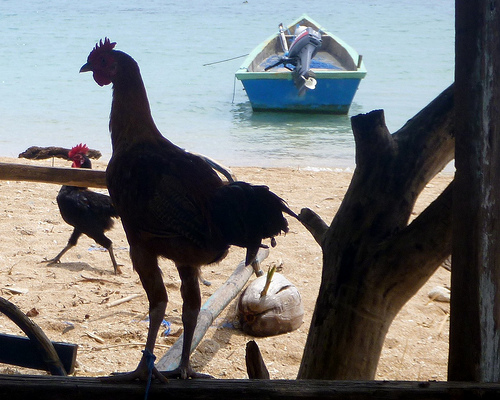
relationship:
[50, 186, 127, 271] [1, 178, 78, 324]
chicken on beach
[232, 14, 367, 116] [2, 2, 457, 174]
boat in water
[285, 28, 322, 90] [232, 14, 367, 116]
motor on boat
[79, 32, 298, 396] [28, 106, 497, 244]
chicken walking on beach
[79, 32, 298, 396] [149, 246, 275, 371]
chicken standing on log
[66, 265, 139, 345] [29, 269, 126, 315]
sticks on sand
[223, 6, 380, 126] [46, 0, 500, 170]
boat in water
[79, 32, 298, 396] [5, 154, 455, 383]
chicken on sand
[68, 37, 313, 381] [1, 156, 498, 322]
chicken on beach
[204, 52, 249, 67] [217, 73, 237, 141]
rope to anchor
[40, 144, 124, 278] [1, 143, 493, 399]
chicken on beach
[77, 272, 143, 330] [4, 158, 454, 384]
sticks in dirt